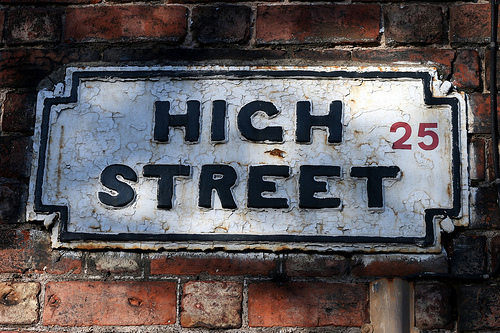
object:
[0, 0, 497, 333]
bricks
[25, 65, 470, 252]
placque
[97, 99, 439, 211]
writing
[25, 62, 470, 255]
sign